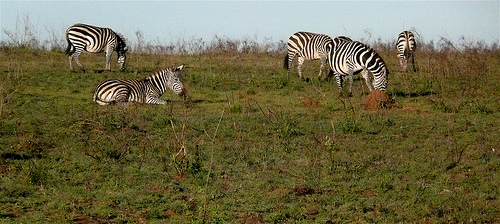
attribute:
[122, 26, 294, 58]
sticks — dead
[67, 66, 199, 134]
zebra — laying down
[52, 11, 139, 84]
zebra — eating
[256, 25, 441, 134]
zebras — eating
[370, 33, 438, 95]
zebras — eating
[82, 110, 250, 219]
sticks — several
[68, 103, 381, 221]
shrubs — small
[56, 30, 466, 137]
zebras — eating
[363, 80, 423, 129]
shrub — brown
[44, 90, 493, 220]
pasture — large, grass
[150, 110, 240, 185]
twigs — tall, dried, sticking out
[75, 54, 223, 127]
zebra — laying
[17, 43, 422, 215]
grass — brown, green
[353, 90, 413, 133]
dirt — brown, piled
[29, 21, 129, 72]
belly — curved, striped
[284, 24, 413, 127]
zebra — striped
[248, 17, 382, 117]
zebra — striped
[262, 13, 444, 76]
zebra — striped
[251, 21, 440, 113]
zebra — striped